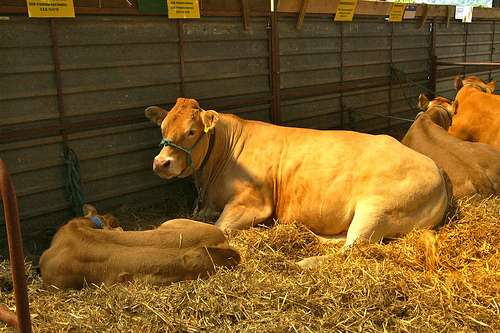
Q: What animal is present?
A: Cow.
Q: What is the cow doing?
A: Sitting down.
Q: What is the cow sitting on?
A: Hay.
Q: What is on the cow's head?
A: Rope.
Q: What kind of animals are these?
A: Cows.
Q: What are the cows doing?
A: Laying down.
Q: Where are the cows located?
A: In the barn.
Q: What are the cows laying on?
A: Hay.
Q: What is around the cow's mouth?
A: Leash.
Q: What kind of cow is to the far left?
A: A calf.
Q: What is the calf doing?
A: Sleeping.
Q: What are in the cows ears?
A: Tags.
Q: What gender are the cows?
A: Females.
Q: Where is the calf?
A: Next to big cow.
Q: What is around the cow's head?
A: Rope.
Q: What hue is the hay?
A: Brown.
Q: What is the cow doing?
A: Laying.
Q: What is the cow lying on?
A: On hay.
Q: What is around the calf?
A: A blue collar.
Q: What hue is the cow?
A: Tan.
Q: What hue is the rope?
A: Green.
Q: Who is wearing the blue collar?
A: The calf.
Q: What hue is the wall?
A: Brown.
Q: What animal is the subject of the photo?
A: Cow.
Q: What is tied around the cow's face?
A: Rope.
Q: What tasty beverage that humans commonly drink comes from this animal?
A: Milk.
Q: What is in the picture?
A: A barn.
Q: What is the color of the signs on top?
A: Yellow.